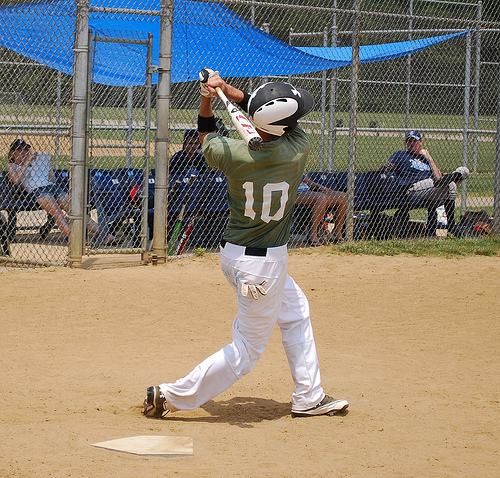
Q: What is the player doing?
A: Swinging the bat.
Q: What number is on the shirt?
A: 10.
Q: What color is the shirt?
A: Green.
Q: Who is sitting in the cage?
A: Teammates and fans.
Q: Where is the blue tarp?
A: Over the cage.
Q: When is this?
A: Daytime.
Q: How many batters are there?
A: One.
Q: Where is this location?
A: Ballpark.